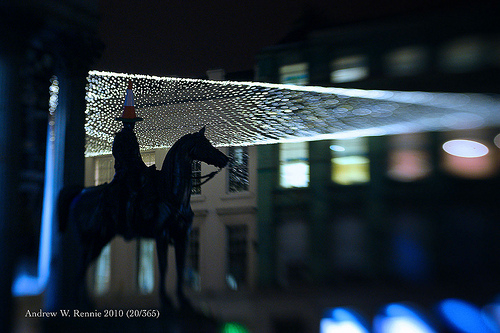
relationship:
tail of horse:
[53, 183, 75, 234] [52, 124, 231, 317]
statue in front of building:
[58, 102, 239, 304] [198, 28, 498, 288]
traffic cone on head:
[117, 80, 137, 117] [118, 120, 138, 130]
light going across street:
[438, 129, 490, 161] [38, 184, 474, 320]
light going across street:
[327, 62, 367, 89] [38, 184, 474, 320]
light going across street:
[327, 150, 374, 187] [38, 184, 474, 320]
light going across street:
[275, 156, 310, 188] [38, 184, 474, 320]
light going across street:
[371, 300, 438, 330] [38, 184, 474, 320]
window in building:
[223, 222, 251, 292] [74, 67, 256, 297]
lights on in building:
[262, 66, 469, 234] [315, 144, 454, 242]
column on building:
[51, 57, 89, 268] [8, 2, 494, 330]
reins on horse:
[177, 152, 233, 210] [21, 130, 241, 210]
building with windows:
[2, 28, 478, 299] [275, 134, 469, 184]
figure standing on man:
[53, 78, 248, 298] [110, 82, 155, 243]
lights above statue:
[55, 57, 270, 147] [48, 88, 235, 314]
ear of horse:
[197, 122, 209, 137] [56, 122, 234, 308]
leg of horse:
[168, 240, 197, 303] [52, 124, 231, 317]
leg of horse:
[147, 226, 177, 310] [48, 127, 243, 325]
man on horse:
[51, 134, 213, 249] [52, 124, 231, 317]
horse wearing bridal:
[56, 122, 234, 308] [183, 150, 226, 187]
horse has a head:
[56, 122, 234, 308] [190, 125, 230, 170]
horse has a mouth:
[56, 122, 234, 308] [212, 151, 228, 167]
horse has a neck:
[52, 124, 231, 317] [157, 158, 186, 189]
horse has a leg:
[52, 124, 231, 317] [149, 240, 178, 314]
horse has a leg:
[52, 124, 231, 317] [174, 239, 191, 306]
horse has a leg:
[52, 124, 231, 317] [70, 242, 100, 311]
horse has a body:
[56, 122, 234, 308] [66, 182, 195, 239]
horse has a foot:
[56, 122, 234, 308] [156, 291, 176, 308]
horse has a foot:
[56, 122, 234, 308] [176, 294, 194, 312]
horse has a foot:
[56, 122, 234, 308] [82, 296, 98, 314]